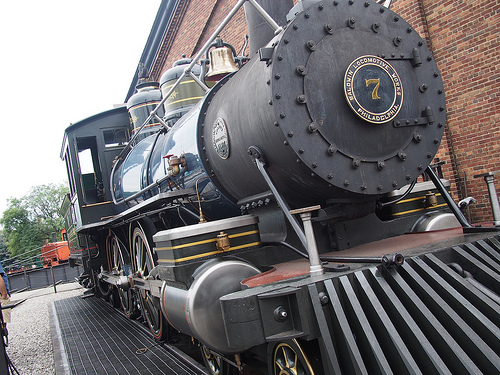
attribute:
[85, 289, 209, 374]
tracks — train, black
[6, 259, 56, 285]
fence — black, wooden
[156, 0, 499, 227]
wall — brick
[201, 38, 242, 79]
bell — gold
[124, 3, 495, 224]
wall — brick